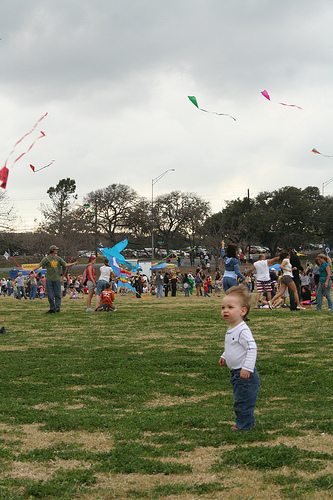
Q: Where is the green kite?
A: Air.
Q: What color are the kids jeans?
A: Blue.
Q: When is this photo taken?
A: Daytime.